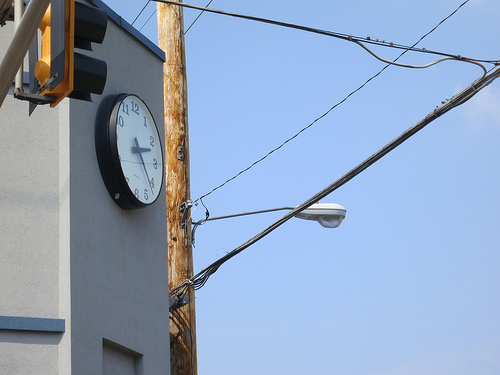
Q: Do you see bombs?
A: No, there are no bombs.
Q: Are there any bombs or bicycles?
A: No, there are no bombs or bicycles.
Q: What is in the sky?
A: The clouds are in the sky.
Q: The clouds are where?
A: The clouds are in the sky.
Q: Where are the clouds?
A: The clouds are in the sky.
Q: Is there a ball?
A: No, there are no balls.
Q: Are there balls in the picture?
A: No, there are no balls.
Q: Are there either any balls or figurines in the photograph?
A: No, there are no balls or figurines.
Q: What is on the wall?
A: The decoration is on the wall.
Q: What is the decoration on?
A: The decoration is on the wall.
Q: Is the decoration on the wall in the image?
A: Yes, the decoration is on the wall.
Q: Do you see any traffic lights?
A: Yes, there is a traffic light.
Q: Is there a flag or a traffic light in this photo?
A: Yes, there is a traffic light.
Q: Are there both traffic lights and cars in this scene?
A: No, there is a traffic light but no cars.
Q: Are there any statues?
A: No, there are no statues.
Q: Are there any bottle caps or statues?
A: No, there are no statues or bottle caps.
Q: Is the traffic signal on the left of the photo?
A: Yes, the traffic signal is on the left of the image.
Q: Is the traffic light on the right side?
A: No, the traffic light is on the left of the image.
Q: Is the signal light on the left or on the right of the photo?
A: The signal light is on the left of the image.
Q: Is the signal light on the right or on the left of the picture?
A: The signal light is on the left of the image.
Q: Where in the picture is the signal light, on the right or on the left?
A: The signal light is on the left of the image.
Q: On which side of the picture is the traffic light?
A: The traffic light is on the left of the image.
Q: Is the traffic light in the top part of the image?
A: Yes, the traffic light is in the top of the image.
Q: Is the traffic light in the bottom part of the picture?
A: No, the traffic light is in the top of the image.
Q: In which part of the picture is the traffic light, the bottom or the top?
A: The traffic light is in the top of the image.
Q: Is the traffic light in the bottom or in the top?
A: The traffic light is in the top of the image.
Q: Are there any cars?
A: No, there are no cars.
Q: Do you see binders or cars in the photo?
A: No, there are no cars or binders.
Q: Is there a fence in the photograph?
A: No, there are no fences.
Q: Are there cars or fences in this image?
A: No, there are no fences or cars.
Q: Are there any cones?
A: No, there are no cones.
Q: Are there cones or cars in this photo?
A: No, there are no cones or cars.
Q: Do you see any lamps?
A: Yes, there is a lamp.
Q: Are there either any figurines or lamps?
A: Yes, there is a lamp.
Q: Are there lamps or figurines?
A: Yes, there is a lamp.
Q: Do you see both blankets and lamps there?
A: No, there is a lamp but no blankets.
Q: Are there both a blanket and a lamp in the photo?
A: No, there is a lamp but no blankets.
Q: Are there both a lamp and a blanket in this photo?
A: No, there is a lamp but no blankets.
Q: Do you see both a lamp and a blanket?
A: No, there is a lamp but no blankets.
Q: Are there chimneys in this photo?
A: No, there are no chimneys.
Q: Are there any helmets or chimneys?
A: No, there are no chimneys or helmets.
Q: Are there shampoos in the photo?
A: No, there are no shampoos.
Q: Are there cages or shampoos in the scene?
A: No, there are no shampoos or cages.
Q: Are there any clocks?
A: Yes, there is a clock.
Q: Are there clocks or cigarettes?
A: Yes, there is a clock.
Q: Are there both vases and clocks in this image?
A: No, there is a clock but no vases.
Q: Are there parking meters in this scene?
A: No, there are no parking meters.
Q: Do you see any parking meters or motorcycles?
A: No, there are no parking meters or motorcycles.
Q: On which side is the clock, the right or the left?
A: The clock is on the left of the image.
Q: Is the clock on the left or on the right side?
A: The clock is on the left of the image.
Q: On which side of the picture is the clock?
A: The clock is on the left of the image.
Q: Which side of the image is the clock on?
A: The clock is on the left of the image.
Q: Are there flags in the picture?
A: No, there are no flags.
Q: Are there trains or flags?
A: No, there are no flags or trains.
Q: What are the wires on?
A: The wires are on the pole.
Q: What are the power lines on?
A: The wires are on the pole.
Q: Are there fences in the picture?
A: No, there are no fences.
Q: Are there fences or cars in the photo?
A: No, there are no fences or cars.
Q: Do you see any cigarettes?
A: No, there are no cigarettes.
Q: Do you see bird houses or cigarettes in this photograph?
A: No, there are no cigarettes or bird houses.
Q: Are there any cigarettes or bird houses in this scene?
A: No, there are no cigarettes or bird houses.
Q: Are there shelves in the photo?
A: No, there are no shelves.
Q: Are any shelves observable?
A: No, there are no shelves.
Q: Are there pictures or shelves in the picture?
A: No, there are no shelves or pictures.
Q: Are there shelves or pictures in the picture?
A: No, there are no shelves or pictures.